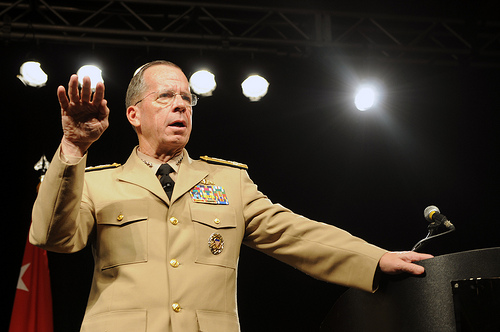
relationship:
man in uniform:
[28, 59, 435, 331] [28, 143, 389, 331]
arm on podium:
[243, 166, 435, 294] [389, 245, 499, 331]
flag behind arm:
[8, 179, 55, 332] [28, 73, 110, 252]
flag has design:
[8, 179, 55, 332] [15, 263, 30, 292]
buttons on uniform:
[113, 213, 221, 312] [28, 143, 389, 331]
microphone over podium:
[413, 205, 455, 252] [389, 245, 499, 331]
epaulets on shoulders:
[85, 156, 249, 170] [84, 161, 252, 204]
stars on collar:
[142, 155, 182, 168] [136, 148, 185, 174]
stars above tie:
[142, 155, 182, 168] [158, 163, 176, 201]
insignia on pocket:
[208, 232, 224, 255] [189, 203, 238, 270]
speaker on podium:
[451, 277, 498, 331] [389, 245, 499, 331]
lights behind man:
[20, 58, 380, 112] [28, 59, 435, 331]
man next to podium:
[28, 59, 435, 331] [389, 245, 499, 331]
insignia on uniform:
[208, 232, 224, 255] [28, 143, 389, 331]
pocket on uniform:
[189, 203, 238, 270] [28, 143, 389, 331]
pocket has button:
[189, 203, 238, 270] [214, 218, 221, 223]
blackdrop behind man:
[0, 0, 498, 332] [28, 59, 435, 331]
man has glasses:
[28, 59, 435, 331] [135, 88, 197, 108]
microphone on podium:
[413, 205, 455, 252] [389, 245, 499, 331]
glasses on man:
[135, 88, 197, 108] [28, 59, 435, 331]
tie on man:
[158, 163, 176, 201] [28, 59, 435, 331]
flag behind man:
[8, 179, 55, 332] [28, 59, 435, 331]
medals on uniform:
[188, 177, 230, 205] [28, 143, 389, 331]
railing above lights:
[0, 0, 499, 72] [20, 58, 380, 112]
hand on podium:
[378, 250, 435, 276] [389, 245, 499, 331]